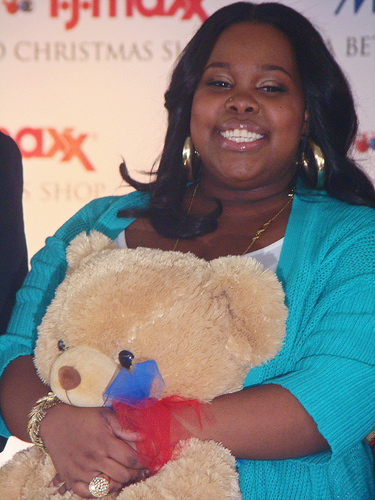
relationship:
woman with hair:
[19, 27, 352, 496] [282, 11, 348, 153]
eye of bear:
[123, 344, 134, 365] [0, 229, 289, 499]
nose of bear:
[53, 360, 91, 407] [0, 229, 289, 499]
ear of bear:
[218, 244, 302, 365] [0, 229, 289, 499]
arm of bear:
[0, 446, 55, 498] [0, 229, 289, 499]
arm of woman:
[15, 238, 113, 498] [19, 27, 352, 496]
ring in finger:
[97, 476, 114, 493] [74, 478, 133, 494]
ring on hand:
[97, 476, 114, 493] [53, 417, 116, 496]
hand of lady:
[53, 417, 116, 496] [28, 25, 354, 460]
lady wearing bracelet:
[28, 25, 354, 460] [23, 393, 72, 447]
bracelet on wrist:
[23, 393, 72, 447] [30, 398, 58, 455]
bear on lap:
[0, 229, 289, 499] [53, 433, 374, 499]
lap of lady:
[53, 433, 374, 499] [28, 25, 354, 460]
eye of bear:
[48, 334, 73, 359] [0, 229, 289, 499]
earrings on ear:
[295, 141, 322, 199] [301, 96, 313, 146]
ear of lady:
[301, 96, 313, 146] [28, 25, 354, 460]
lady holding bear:
[28, 25, 354, 460] [0, 229, 289, 499]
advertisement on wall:
[55, 3, 228, 25] [20, 9, 375, 224]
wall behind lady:
[20, 9, 375, 224] [28, 25, 354, 460]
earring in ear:
[172, 137, 204, 192] [180, 87, 182, 135]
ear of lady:
[180, 87, 182, 135] [28, 25, 354, 460]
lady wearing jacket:
[28, 25, 354, 460] [32, 198, 344, 499]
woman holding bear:
[19, 27, 352, 496] [0, 229, 289, 499]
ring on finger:
[97, 476, 114, 493] [74, 478, 133, 494]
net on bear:
[102, 358, 217, 473] [39, 236, 247, 499]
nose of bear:
[53, 360, 91, 407] [39, 236, 247, 499]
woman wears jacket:
[19, 27, 352, 496] [0, 176, 375, 500]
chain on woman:
[242, 191, 295, 255] [19, 27, 352, 496]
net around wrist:
[125, 378, 201, 485] [138, 368, 201, 470]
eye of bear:
[119, 350, 134, 370] [39, 236, 247, 499]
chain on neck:
[226, 214, 315, 249] [176, 165, 296, 203]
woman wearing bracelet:
[19, 27, 352, 496] [23, 393, 72, 447]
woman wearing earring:
[19, 27, 352, 496] [172, 137, 204, 192]